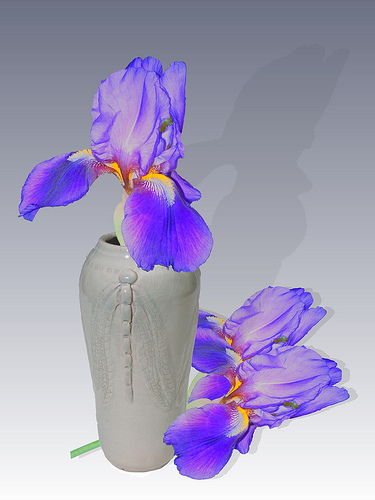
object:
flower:
[18, 59, 213, 273]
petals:
[163, 398, 247, 479]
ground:
[1, 285, 373, 498]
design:
[90, 269, 177, 409]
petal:
[120, 172, 212, 274]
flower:
[186, 286, 327, 377]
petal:
[89, 57, 184, 180]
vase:
[78, 233, 199, 474]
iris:
[13, 36, 220, 220]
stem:
[70, 438, 100, 458]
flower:
[163, 344, 348, 481]